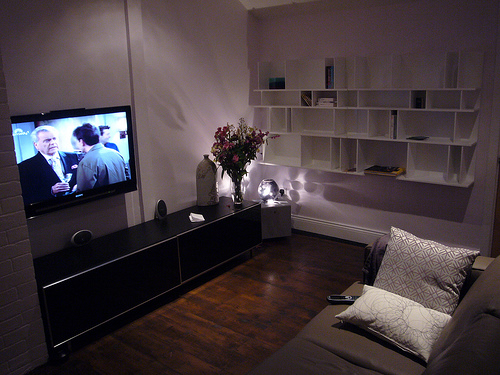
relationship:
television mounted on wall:
[10, 102, 138, 218] [1, 0, 248, 260]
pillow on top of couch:
[372, 222, 479, 317] [229, 223, 498, 372]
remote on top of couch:
[326, 292, 364, 306] [229, 223, 498, 372]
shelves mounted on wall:
[249, 50, 483, 186] [247, 1, 499, 257]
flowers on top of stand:
[208, 117, 279, 206] [34, 193, 262, 357]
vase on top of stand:
[228, 170, 247, 205] [34, 193, 262, 357]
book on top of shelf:
[404, 133, 427, 141] [400, 133, 452, 145]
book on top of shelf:
[364, 164, 403, 177] [357, 163, 405, 180]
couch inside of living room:
[229, 223, 498, 372] [1, 0, 497, 373]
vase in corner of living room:
[256, 176, 279, 205] [1, 0, 497, 373]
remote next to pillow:
[326, 292, 364, 306] [336, 284, 453, 364]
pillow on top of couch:
[336, 284, 453, 364] [229, 223, 498, 372]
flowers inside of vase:
[208, 117, 279, 206] [228, 170, 247, 205]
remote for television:
[326, 292, 364, 306] [10, 102, 138, 218]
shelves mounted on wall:
[249, 50, 483, 186] [1, 0, 248, 260]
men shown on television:
[17, 122, 129, 206] [10, 102, 138, 218]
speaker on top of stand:
[71, 230, 94, 248] [34, 193, 262, 357]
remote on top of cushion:
[326, 292, 364, 306] [297, 278, 428, 374]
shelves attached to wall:
[249, 50, 483, 186] [247, 1, 499, 257]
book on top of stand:
[186, 208, 206, 223] [34, 193, 262, 357]